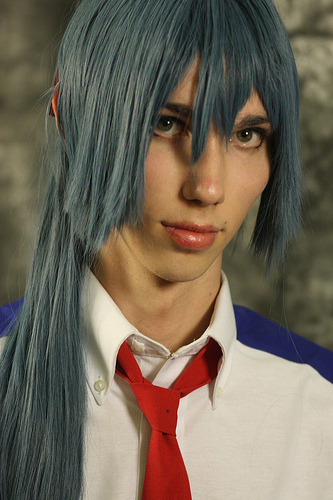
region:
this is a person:
[9, 3, 331, 496]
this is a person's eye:
[145, 87, 198, 144]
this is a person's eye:
[231, 82, 271, 155]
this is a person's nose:
[177, 135, 243, 220]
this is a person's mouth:
[150, 213, 223, 251]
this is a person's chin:
[127, 248, 223, 283]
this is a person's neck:
[93, 278, 235, 349]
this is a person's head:
[31, 2, 331, 284]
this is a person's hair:
[0, 3, 332, 498]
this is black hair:
[66, 3, 314, 56]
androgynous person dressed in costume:
[0, 0, 332, 499]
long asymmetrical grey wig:
[0, 0, 308, 499]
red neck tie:
[115, 338, 221, 498]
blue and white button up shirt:
[0, 262, 331, 498]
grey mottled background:
[0, 0, 332, 347]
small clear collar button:
[93, 380, 107, 390]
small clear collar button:
[214, 385, 222, 399]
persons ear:
[50, 78, 75, 162]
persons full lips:
[161, 217, 222, 253]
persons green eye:
[229, 123, 268, 152]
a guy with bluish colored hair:
[23, 6, 317, 477]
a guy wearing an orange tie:
[31, 5, 304, 481]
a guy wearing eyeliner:
[134, 93, 281, 163]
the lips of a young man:
[151, 212, 234, 257]